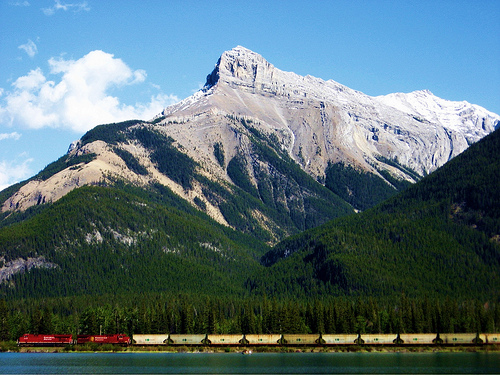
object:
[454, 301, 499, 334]
trees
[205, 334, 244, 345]
cars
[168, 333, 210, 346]
cars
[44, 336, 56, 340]
white writing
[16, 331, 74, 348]
train car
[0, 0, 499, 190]
sky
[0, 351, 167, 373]
water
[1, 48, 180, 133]
cloud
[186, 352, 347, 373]
water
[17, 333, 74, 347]
red train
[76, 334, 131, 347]
red train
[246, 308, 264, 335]
tree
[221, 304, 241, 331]
tree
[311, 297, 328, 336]
tree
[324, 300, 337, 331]
tree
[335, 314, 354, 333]
tree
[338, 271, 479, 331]
ground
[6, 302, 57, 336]
trees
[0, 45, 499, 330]
mountain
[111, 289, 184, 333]
trees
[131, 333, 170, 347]
cars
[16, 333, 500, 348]
bus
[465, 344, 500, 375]
water